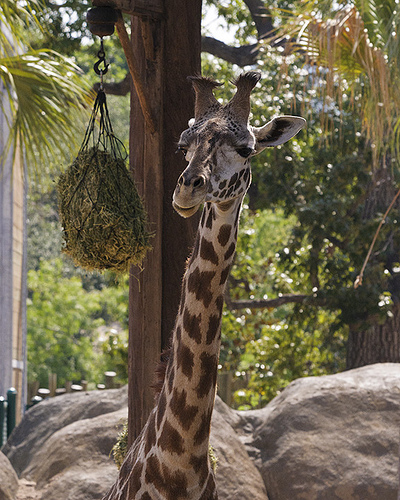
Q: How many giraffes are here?
A: One.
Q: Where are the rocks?
A: Behind the giraffe.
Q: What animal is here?
A: Giraffe.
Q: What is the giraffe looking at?
A: A clump of hay.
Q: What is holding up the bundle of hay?
A: A net.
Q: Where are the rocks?
A: Behind the giraffe.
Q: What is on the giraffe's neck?
A: Spots.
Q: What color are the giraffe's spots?
A: Brown.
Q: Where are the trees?
A: Behind the giraffe.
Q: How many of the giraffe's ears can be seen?
A: One.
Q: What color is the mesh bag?
A: Black.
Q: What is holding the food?
A: Black net.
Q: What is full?
A: The net of food.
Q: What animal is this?
A: Giraffe.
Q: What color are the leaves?
A: Green.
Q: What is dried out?
A: Palm frond.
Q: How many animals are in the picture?
A: One.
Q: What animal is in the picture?
A: A giraffe.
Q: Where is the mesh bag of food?
A: Hanging from a wooden post.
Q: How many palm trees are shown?
A: Two.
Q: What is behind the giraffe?
A: Gray rocks.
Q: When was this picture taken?
A: During the daytime.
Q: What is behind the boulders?
A: Trees.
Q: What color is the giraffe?
A: Brown and tan.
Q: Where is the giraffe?
A: In an enclosure.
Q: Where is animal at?
A: Zoo.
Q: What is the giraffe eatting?
A: Hay.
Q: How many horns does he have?
A: Two.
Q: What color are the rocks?
A: Gray.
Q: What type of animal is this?
A: Giraffe.